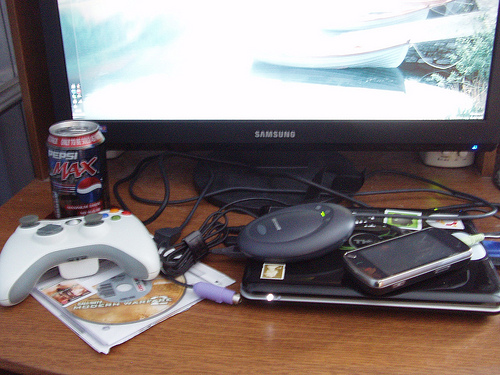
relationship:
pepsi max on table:
[43, 117, 110, 224] [2, 136, 499, 374]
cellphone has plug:
[341, 224, 474, 297] [452, 227, 500, 250]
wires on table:
[110, 153, 499, 308] [2, 136, 499, 374]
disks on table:
[35, 235, 236, 356] [2, 136, 499, 374]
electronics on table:
[2, 200, 500, 320] [2, 136, 499, 374]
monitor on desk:
[33, 0, 498, 151] [2, 139, 499, 374]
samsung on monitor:
[253, 127, 301, 141] [33, 0, 498, 151]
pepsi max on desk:
[43, 117, 110, 224] [2, 139, 499, 374]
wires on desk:
[110, 153, 499, 308] [2, 139, 499, 374]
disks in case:
[35, 235, 236, 356] [28, 233, 233, 354]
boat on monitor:
[227, 2, 437, 70] [33, 0, 498, 151]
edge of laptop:
[238, 288, 499, 313] [238, 199, 499, 317]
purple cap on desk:
[186, 282, 244, 309] [2, 139, 499, 374]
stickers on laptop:
[377, 206, 467, 234] [238, 199, 499, 317]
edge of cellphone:
[339, 252, 381, 292] [341, 224, 474, 297]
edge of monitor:
[77, 119, 497, 152] [33, 0, 498, 151]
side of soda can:
[95, 131, 112, 213] [41, 117, 112, 218]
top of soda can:
[45, 117, 100, 138] [41, 117, 112, 218]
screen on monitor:
[57, 0, 499, 121] [33, 0, 498, 151]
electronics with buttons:
[0, 206, 165, 311] [8, 204, 133, 237]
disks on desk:
[47, 263, 189, 321] [2, 139, 499, 374]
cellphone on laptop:
[341, 224, 474, 297] [238, 199, 499, 317]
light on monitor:
[468, 143, 479, 152] [33, 0, 498, 151]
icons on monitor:
[68, 81, 87, 119] [33, 0, 498, 151]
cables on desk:
[108, 148, 498, 274] [2, 139, 499, 374]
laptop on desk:
[238, 199, 499, 317] [2, 139, 499, 374]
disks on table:
[47, 263, 189, 321] [2, 136, 499, 374]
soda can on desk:
[41, 117, 112, 218] [2, 139, 499, 374]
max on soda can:
[51, 157, 101, 183] [41, 117, 112, 218]